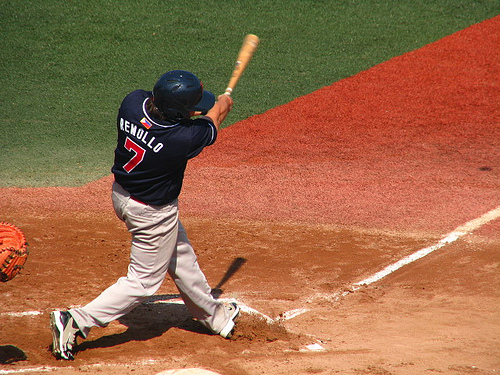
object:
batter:
[48, 70, 238, 362]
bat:
[223, 32, 259, 95]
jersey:
[110, 90, 218, 210]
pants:
[68, 180, 228, 337]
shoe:
[47, 310, 77, 360]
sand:
[0, 215, 498, 374]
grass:
[0, 1, 499, 191]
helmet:
[149, 69, 216, 117]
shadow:
[73, 258, 245, 352]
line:
[264, 206, 498, 324]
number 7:
[122, 137, 146, 175]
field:
[1, 1, 499, 374]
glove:
[0, 221, 27, 280]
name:
[119, 119, 164, 154]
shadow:
[0, 345, 29, 364]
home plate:
[144, 296, 187, 325]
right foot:
[48, 307, 78, 362]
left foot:
[218, 297, 240, 337]